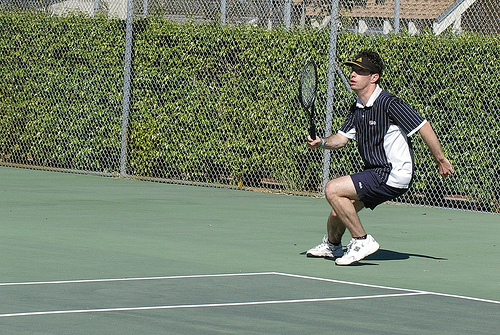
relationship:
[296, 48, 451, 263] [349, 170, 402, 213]
man wearing shorts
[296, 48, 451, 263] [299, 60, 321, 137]
man holding racquet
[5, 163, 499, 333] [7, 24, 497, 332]
court for tennis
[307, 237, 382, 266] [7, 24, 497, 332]
shoes are for tennis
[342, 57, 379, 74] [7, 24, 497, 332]
visor for tennis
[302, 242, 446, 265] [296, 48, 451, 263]
shadow of player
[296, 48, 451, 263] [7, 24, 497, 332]
man playing tennis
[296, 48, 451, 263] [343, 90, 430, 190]
man wearing black and white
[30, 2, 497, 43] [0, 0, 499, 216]
houses behind fence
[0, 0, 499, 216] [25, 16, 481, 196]
bushes outside fence